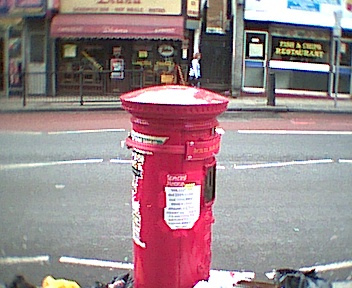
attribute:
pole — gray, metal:
[331, 26, 340, 110]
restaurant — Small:
[244, 32, 272, 66]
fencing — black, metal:
[6, 66, 164, 117]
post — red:
[105, 76, 220, 220]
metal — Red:
[126, 66, 230, 226]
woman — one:
[187, 50, 200, 84]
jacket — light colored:
[188, 59, 199, 75]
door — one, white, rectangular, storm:
[24, 31, 58, 95]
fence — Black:
[2, 64, 148, 110]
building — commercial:
[49, 0, 187, 99]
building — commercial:
[231, 0, 350, 100]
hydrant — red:
[117, 82, 229, 286]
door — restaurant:
[244, 27, 270, 90]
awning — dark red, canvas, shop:
[50, 16, 185, 39]